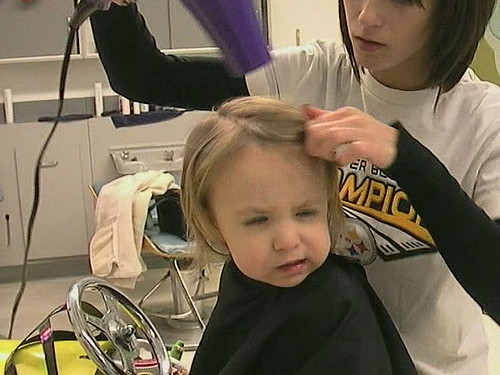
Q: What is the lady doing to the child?
A: Blow drying hair.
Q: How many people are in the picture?
A: Two.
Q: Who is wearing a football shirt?
A: Older lady.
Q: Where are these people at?
A: Salon.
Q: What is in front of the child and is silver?
A: Steering wheel.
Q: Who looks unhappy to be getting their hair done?
A: Child.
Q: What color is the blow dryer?
A: Purple.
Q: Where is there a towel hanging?
A: Chair in background.